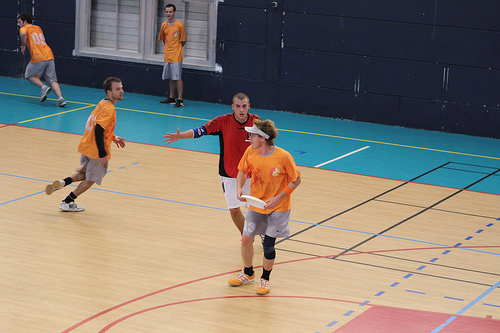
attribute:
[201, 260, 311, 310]
shoes — white , yellow 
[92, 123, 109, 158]
sleeve — black 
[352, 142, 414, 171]
floor — light blue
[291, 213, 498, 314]
line — blue, broken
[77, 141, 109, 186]
short — grey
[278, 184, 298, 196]
band — orange 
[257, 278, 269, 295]
shoe — orange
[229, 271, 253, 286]
shoe — orange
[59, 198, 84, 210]
shoe — orange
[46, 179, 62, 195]
shoe — orange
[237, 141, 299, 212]
shirt — orange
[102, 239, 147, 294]
floor — smooth, brown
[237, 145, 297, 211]
shirt — orange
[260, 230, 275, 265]
leging — black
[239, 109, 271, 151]
visor — white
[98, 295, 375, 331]
curved line — red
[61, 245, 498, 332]
curved line — red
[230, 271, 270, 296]
shoes — white, yellow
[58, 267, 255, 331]
red lines — red 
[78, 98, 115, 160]
shirt — orange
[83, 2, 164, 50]
window — closed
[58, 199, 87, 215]
shoe — white 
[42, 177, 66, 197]
shoe — white 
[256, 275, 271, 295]
shoe — white 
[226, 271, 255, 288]
shoe — white 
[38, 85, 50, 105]
shoe — white 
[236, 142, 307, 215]
shirt — red, black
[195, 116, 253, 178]
jersey — red